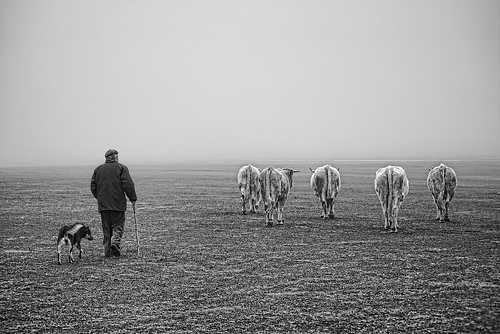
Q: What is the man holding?
A: A stick.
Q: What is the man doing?
A: Walking.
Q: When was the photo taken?
A: Daytime.